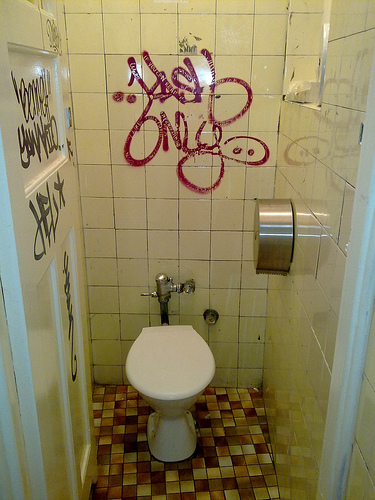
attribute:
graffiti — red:
[101, 32, 277, 197]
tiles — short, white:
[45, 1, 371, 499]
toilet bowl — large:
[120, 320, 222, 421]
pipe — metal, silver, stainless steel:
[155, 304, 175, 325]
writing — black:
[7, 61, 82, 395]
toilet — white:
[118, 318, 222, 465]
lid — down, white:
[123, 322, 219, 405]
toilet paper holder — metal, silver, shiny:
[246, 194, 303, 282]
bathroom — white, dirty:
[35, 2, 372, 499]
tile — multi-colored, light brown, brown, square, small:
[90, 382, 283, 499]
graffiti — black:
[7, 4, 91, 388]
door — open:
[2, 2, 104, 499]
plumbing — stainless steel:
[153, 266, 199, 325]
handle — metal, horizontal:
[140, 289, 160, 301]